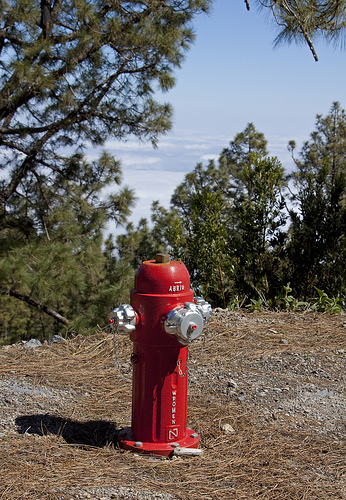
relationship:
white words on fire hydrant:
[170, 388, 178, 423] [106, 250, 211, 462]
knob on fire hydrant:
[166, 301, 204, 339] [106, 250, 211, 462]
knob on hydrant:
[163, 301, 204, 348] [102, 240, 218, 425]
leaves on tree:
[250, 175, 260, 182] [211, 115, 283, 302]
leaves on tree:
[216, 261, 240, 276] [172, 122, 298, 302]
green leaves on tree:
[21, 238, 96, 278] [0, 7, 127, 258]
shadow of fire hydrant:
[17, 410, 128, 452] [106, 250, 210, 456]